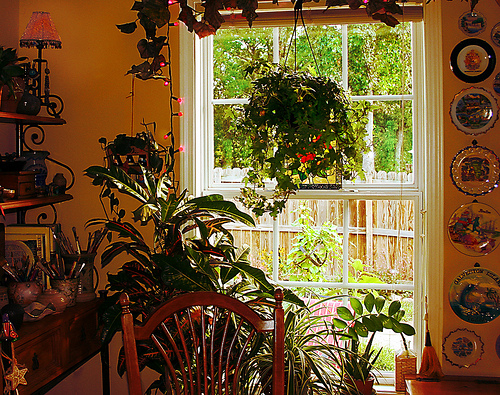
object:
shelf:
[0, 52, 126, 395]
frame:
[5, 223, 61, 292]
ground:
[379, 385, 397, 395]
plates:
[445, 264, 500, 326]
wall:
[437, 3, 498, 373]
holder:
[19, 11, 65, 120]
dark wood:
[27, 330, 78, 371]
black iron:
[44, 94, 65, 116]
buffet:
[0, 48, 113, 393]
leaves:
[388, 300, 402, 317]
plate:
[447, 37, 498, 84]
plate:
[438, 327, 484, 370]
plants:
[111, 0, 167, 58]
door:
[182, 0, 430, 363]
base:
[22, 40, 65, 117]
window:
[212, 22, 276, 99]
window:
[282, 23, 352, 113]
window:
[351, 17, 428, 111]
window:
[336, 93, 422, 184]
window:
[208, 102, 282, 182]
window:
[278, 203, 357, 290]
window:
[203, 198, 278, 295]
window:
[346, 286, 426, 372]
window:
[282, 286, 345, 364]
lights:
[176, 96, 186, 103]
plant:
[83, 118, 170, 183]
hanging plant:
[231, 57, 361, 218]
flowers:
[232, 64, 358, 221]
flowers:
[330, 293, 416, 385]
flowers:
[82, 159, 315, 372]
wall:
[80, 44, 120, 94]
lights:
[178, 146, 188, 152]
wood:
[118, 284, 285, 382]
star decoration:
[0, 361, 31, 389]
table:
[1, 290, 123, 395]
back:
[114, 286, 283, 395]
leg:
[100, 342, 111, 395]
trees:
[210, 21, 411, 172]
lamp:
[16, 11, 65, 118]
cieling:
[8, 1, 484, 31]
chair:
[119, 288, 285, 395]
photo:
[0, 0, 499, 395]